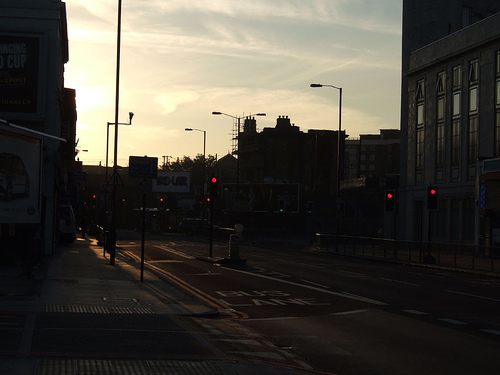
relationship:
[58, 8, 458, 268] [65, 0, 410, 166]
dawn in sky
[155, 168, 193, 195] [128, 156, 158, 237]
sign on building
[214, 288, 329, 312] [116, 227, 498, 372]
writing on pavement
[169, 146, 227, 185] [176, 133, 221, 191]
tree top with leaves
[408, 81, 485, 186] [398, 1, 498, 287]
windows on building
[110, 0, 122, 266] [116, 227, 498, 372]
pole beside pavement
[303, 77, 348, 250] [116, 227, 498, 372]
street light beside pavement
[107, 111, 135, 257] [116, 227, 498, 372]
traffic cam on pavement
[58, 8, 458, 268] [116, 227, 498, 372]
dawn on pavement